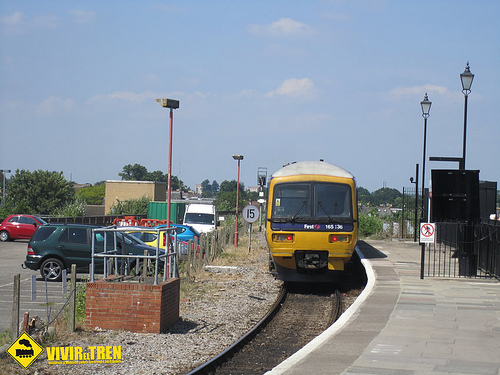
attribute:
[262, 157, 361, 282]
train — yellow, white, grey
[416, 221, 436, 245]
sign — white, red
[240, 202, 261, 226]
sign — round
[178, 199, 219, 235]
van — white, parked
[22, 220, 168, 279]
suv — green, parked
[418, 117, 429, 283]
pole — black, tall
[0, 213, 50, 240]
car — red, small, parked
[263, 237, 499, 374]
platform — brick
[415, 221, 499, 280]
fence — black, metal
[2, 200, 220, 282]
cars — parked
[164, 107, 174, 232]
pole — red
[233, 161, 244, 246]
pole — red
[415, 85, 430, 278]
lamppost — black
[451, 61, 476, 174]
lamppost — black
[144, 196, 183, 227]
storage container — parked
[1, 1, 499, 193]
sky — blue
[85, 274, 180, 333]
structure — brick